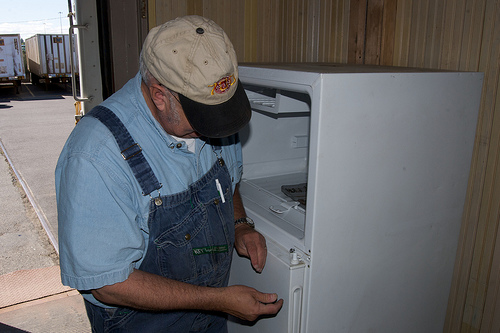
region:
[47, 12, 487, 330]
a person next to the refrigerator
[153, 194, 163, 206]
a button on the person's clothes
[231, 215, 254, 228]
a watch on the wrist of the guy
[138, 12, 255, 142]
a hat on the man's head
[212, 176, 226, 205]
a pen pinned the man's clothe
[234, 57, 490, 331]
a white refrigerator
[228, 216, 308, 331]
a door of the refrigerator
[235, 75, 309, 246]
a top door of the refrigerator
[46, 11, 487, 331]
a guy checking the refrigerator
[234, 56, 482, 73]
a top of the refrigerator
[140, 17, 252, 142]
Light brown hat with a black front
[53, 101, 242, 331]
Man wearing a dungaree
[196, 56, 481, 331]
Tall white refrigerator with a door open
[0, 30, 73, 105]
Trucks parked in a yard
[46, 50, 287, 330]
Man standing with head lowered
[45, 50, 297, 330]
Man standing with hands on the front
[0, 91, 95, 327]
Yard made of concrete material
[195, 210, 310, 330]
Lower door of a refrigerator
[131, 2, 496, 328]
Wall of wooden planks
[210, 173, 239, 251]
White pen stuck in the pocket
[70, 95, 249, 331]
pair of denim overalls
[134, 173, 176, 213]
metal buckle on pair of denim overalls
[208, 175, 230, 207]
white pen in front pocket of denim overall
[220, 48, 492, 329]
white refrigerator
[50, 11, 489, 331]
man repairing refrigerator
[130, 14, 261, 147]
tan and black baseball cap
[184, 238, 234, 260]
green stripe on front pocket of denim overalls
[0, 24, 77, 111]
trucks parked in parking lot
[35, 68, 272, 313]
blue short sleeve shirt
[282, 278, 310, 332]
handle section on side of refrigerator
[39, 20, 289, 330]
man wearing overalls and a hat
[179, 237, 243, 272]
green tag on denim pocket of clothes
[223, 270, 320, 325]
hand on refrigerator white door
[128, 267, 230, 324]
hairy arm with fair pale skin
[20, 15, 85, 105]
back end of a trailer that is parked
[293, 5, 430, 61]
different shades of wood paneled walls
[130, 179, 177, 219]
button and hook for overall strap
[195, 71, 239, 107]
embroidered red and yellow logo on hat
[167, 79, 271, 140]
beige hat with black brim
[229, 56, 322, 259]
inside of white freezer with no door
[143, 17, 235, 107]
tan colored hat on head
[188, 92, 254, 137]
black bill to hat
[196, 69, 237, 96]
red and yellow logo n hat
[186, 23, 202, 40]
black tip of hat top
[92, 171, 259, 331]
denim overalls on man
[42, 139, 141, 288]
blue sleeve of shirt on man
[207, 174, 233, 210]
white pen in pocket of man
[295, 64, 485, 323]
side of white fridge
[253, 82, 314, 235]
door taken off freezer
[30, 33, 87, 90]
back of large semi trucks